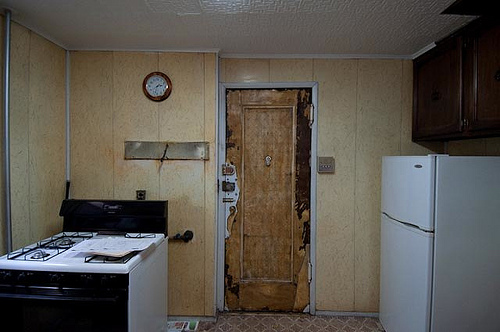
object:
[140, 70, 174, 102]
clock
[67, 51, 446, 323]
wall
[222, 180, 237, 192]
locks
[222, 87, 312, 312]
door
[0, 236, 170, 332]
stove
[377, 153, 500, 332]
fridge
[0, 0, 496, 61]
ceiling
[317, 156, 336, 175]
intercom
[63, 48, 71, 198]
pipe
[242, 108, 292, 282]
hole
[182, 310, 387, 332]
floor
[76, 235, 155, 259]
papers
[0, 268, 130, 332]
range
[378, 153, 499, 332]
freezer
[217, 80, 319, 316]
doorway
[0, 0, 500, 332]
kitchen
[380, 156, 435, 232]
door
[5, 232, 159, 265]
cooker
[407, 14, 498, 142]
cabinets